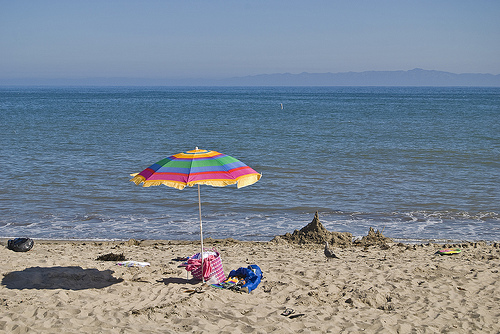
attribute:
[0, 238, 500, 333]
sand — brown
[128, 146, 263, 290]
umbrella — striped, colorful, open, multi-colored, green, blue, yellow, pink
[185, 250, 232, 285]
beach bag — colorful, checkered, red, white, pink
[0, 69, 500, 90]
land — mountainous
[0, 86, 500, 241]
water — blue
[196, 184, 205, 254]
umbrella pole — metal, white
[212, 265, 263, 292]
backpack — blue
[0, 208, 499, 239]
waves — small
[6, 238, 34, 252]
object — dark